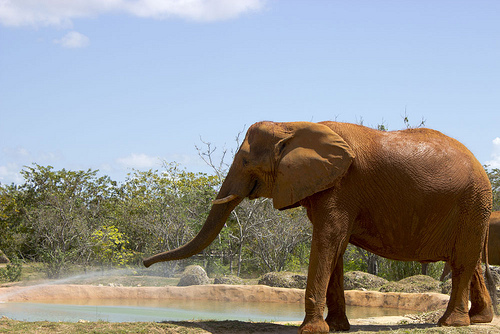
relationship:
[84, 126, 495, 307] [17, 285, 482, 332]
elephant walking across path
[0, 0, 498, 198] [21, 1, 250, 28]
sky has clouds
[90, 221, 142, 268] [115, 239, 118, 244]
bush has foliage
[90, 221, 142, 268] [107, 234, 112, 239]
bush has foliage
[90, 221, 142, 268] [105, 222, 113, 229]
bush has foliage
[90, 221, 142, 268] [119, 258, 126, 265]
bush has foliage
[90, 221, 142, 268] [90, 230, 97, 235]
bush has foliage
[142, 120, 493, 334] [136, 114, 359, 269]
elephant has head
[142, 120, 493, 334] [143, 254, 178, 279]
elephant has nose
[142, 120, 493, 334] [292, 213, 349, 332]
elephant has leg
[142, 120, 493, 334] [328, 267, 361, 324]
elephant has leg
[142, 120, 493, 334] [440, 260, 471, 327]
elephant has leg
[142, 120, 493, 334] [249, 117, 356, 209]
elephant has ear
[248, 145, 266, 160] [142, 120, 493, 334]
eye of elephant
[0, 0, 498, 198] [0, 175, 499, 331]
sky above land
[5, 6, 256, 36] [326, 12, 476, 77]
clouds in sky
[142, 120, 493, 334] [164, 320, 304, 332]
elephant has shadow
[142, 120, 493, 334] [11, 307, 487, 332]
elephant on path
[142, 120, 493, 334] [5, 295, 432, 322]
elephant sprays water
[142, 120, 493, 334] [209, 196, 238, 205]
elephant has tusks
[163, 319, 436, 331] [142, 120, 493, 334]
shadow of elephant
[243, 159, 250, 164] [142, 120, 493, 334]
eye of elephant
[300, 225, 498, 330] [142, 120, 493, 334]
legs of elephant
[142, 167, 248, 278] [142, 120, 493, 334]
trunk of elephant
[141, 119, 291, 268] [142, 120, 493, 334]
head of elephant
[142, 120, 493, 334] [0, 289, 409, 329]
elephant next to hole